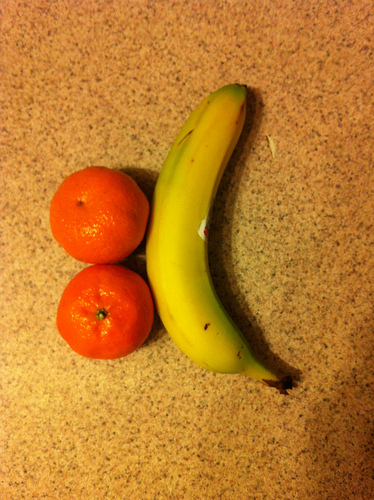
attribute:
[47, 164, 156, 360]
oranges — round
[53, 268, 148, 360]
tangerine — orange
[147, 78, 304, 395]
banana — yellow, green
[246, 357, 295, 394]
stem — brown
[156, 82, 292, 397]
banana — yellow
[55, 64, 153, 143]
table — wooden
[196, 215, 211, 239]
sticker — white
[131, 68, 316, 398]
banana — yellow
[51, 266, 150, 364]
clementine — rough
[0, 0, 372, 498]
floor — brown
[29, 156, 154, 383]
fruit — orange